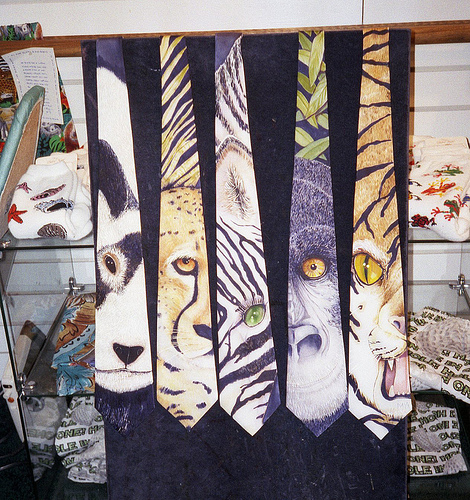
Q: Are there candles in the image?
A: No, there are no candles.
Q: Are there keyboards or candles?
A: No, there are no candles or keyboards.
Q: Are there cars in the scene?
A: No, there are no cars.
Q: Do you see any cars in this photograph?
A: No, there are no cars.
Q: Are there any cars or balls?
A: No, there are no cars or balls.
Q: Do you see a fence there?
A: No, there are no fences.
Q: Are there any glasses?
A: No, there are no glasses.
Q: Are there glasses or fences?
A: No, there are no glasses or fences.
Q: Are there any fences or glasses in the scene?
A: No, there are no glasses or fences.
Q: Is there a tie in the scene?
A: Yes, there is a tie.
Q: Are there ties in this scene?
A: Yes, there is a tie.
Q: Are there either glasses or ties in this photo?
A: Yes, there is a tie.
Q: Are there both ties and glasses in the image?
A: No, there is a tie but no glasses.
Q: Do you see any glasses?
A: No, there are no glasses.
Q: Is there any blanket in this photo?
A: Yes, there is a blanket.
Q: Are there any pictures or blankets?
A: Yes, there is a blanket.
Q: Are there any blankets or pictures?
A: Yes, there is a blanket.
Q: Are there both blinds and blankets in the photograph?
A: No, there is a blanket but no blinds.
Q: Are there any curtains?
A: No, there are no curtains.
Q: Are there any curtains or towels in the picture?
A: No, there are no curtains or towels.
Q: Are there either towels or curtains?
A: No, there are no curtains or towels.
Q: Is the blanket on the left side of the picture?
A: Yes, the blanket is on the left of the image.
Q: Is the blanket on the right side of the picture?
A: No, the blanket is on the left of the image.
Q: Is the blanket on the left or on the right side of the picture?
A: The blanket is on the left of the image.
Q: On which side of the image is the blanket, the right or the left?
A: The blanket is on the left of the image.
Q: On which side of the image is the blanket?
A: The blanket is on the left of the image.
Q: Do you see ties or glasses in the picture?
A: Yes, there is a tie.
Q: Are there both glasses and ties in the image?
A: No, there is a tie but no glasses.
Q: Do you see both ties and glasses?
A: No, there is a tie but no glasses.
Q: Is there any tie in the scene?
A: Yes, there is a tie.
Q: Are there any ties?
A: Yes, there is a tie.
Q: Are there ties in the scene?
A: Yes, there is a tie.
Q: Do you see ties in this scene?
A: Yes, there is a tie.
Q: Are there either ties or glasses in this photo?
A: Yes, there is a tie.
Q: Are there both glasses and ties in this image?
A: No, there is a tie but no glasses.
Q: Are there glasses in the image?
A: No, there are no glasses.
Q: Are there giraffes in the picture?
A: No, there are no giraffes.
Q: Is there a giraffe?
A: No, there are no giraffes.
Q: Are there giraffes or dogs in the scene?
A: No, there are no giraffes or dogs.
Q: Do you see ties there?
A: Yes, there is a tie.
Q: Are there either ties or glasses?
A: Yes, there is a tie.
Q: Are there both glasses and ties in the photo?
A: No, there is a tie but no glasses.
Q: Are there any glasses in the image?
A: No, there are no glasses.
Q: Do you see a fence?
A: No, there are no fences.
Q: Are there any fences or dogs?
A: No, there are no fences or dogs.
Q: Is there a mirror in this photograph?
A: No, there are no mirrors.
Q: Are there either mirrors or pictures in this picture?
A: No, there are no mirrors or pictures.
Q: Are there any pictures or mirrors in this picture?
A: No, there are no mirrors or pictures.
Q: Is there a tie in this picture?
A: Yes, there is a tie.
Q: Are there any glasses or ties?
A: Yes, there is a tie.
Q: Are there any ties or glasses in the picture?
A: Yes, there is a tie.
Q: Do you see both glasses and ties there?
A: No, there is a tie but no glasses.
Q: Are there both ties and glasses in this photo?
A: No, there is a tie but no glasses.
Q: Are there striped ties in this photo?
A: Yes, there is a striped tie.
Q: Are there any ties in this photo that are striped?
A: Yes, there is a striped tie.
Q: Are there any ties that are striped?
A: Yes, there is a tie that is striped.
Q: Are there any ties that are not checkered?
A: Yes, there is a striped tie.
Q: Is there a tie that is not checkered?
A: Yes, there is a striped tie.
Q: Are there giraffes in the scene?
A: No, there are no giraffes.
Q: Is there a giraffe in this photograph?
A: No, there are no giraffes.